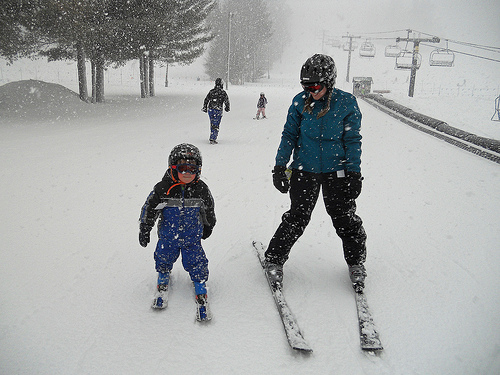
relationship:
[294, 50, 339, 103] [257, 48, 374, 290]
head of adult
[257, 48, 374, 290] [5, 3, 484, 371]
adult on slope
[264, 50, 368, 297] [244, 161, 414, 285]
adult wearing pants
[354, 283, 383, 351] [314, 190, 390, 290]
ski on foot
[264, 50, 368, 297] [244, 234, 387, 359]
adult on skis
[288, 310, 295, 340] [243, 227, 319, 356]
snow on ski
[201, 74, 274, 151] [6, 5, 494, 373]
people in snow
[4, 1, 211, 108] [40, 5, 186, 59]
tree covered in snow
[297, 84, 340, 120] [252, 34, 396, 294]
hair on lady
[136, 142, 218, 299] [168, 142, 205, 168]
child wearing cap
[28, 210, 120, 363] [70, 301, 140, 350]
ground covered snow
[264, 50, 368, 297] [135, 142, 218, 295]
adult watching child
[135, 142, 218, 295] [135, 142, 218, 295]
child of child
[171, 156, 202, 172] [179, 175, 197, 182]
goggles to protect eyes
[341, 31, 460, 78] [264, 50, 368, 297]
lift to carry adult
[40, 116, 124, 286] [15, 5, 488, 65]
snow falling from sky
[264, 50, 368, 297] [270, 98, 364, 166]
adult wearing jacket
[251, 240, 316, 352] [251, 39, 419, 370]
ski of lady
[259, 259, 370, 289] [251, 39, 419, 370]
boots of lady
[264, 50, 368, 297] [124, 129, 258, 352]
adult talking to child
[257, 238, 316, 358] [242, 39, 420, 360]
ski for athletic person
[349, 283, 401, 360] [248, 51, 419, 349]
ski for athletic person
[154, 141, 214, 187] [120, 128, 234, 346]
head of child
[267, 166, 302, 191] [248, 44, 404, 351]
glove hand on adult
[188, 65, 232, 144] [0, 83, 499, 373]
adult person on slope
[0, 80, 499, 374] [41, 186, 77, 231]
snow  white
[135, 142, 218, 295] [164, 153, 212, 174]
child wearing goggles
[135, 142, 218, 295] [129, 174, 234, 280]
child in a ski suit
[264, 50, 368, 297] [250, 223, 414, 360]
adult on skis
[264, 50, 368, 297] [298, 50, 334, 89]
adult wearing a helmet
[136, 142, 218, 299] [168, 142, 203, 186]
child wearing a cap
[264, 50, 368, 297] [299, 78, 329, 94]
adult wearing ski goggles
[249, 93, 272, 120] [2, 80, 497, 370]
child walking on snow